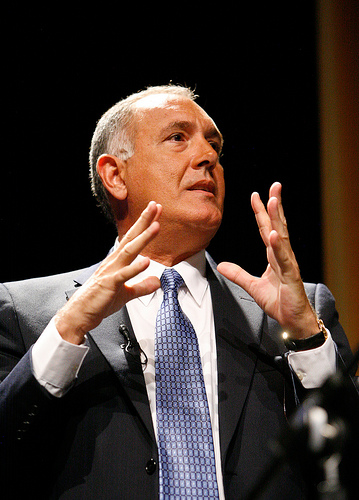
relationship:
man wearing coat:
[104, 79, 216, 227] [0, 235, 355, 498]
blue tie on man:
[151, 268, 219, 499] [0, 79, 358, 498]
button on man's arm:
[32, 398, 43, 411] [0, 323, 102, 467]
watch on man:
[284, 325, 318, 349] [103, 94, 240, 261]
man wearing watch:
[0, 79, 358, 498] [284, 325, 318, 349]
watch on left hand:
[284, 325, 318, 349] [215, 178, 307, 326]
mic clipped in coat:
[114, 320, 147, 363] [0, 235, 355, 498]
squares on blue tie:
[191, 421, 200, 432] [151, 268, 219, 499]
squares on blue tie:
[165, 321, 178, 334] [151, 268, 219, 499]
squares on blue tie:
[186, 434, 205, 449] [151, 268, 219, 499]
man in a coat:
[0, 79, 358, 498] [0, 235, 355, 498]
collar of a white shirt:
[116, 247, 217, 314] [121, 256, 225, 498]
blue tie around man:
[151, 268, 219, 499] [68, 73, 314, 350]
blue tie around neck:
[151, 268, 219, 499] [126, 230, 205, 268]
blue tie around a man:
[151, 268, 219, 499] [0, 79, 358, 498]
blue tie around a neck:
[151, 268, 219, 499] [108, 231, 215, 268]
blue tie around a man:
[151, 268, 219, 499] [83, 83, 313, 328]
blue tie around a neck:
[151, 268, 219, 499] [107, 233, 215, 292]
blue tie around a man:
[151, 268, 219, 499] [131, 208, 216, 252]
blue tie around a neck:
[151, 268, 219, 499] [107, 235, 215, 298]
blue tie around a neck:
[151, 268, 219, 499] [111, 232, 211, 275]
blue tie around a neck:
[151, 268, 220, 498] [130, 248, 189, 263]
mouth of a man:
[174, 168, 236, 202] [0, 79, 358, 498]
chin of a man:
[171, 201, 223, 233] [92, 49, 251, 277]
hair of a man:
[88, 81, 199, 221] [0, 79, 358, 498]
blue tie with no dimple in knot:
[151, 268, 219, 499] [122, 271, 205, 350]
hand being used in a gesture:
[216, 181, 316, 333] [50, 252, 294, 391]